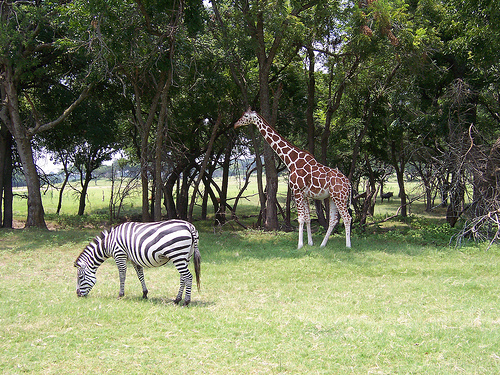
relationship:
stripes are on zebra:
[118, 223, 191, 266] [75, 220, 204, 307]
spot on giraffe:
[288, 150, 299, 162] [234, 107, 358, 249]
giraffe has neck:
[234, 107, 358, 249] [257, 120, 299, 170]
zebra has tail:
[75, 220, 204, 307] [191, 224, 201, 290]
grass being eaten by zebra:
[0, 229, 499, 374] [75, 220, 204, 307]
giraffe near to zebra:
[234, 107, 358, 249] [75, 220, 204, 307]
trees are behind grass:
[3, 2, 499, 229] [0, 229, 499, 374]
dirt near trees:
[12, 214, 59, 233] [3, 2, 499, 229]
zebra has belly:
[75, 220, 204, 307] [125, 250, 168, 269]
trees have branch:
[3, 2, 499, 229] [29, 84, 91, 131]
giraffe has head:
[234, 107, 358, 249] [233, 107, 257, 129]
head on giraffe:
[233, 107, 257, 129] [234, 107, 358, 249]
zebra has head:
[75, 220, 204, 307] [75, 262, 98, 297]